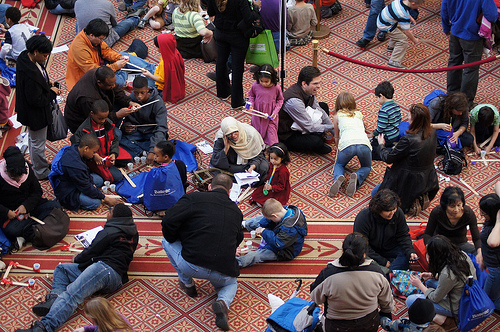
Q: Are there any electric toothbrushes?
A: No, there are no electric toothbrushes.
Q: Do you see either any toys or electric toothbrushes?
A: No, there are no electric toothbrushes or toys.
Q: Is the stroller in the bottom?
A: Yes, the stroller is in the bottom of the image.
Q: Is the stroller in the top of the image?
A: No, the stroller is in the bottom of the image.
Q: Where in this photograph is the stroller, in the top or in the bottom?
A: The stroller is in the bottom of the image.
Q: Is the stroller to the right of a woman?
A: No, the stroller is to the left of a woman.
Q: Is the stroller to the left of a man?
A: No, the stroller is to the right of a man.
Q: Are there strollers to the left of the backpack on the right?
A: Yes, there is a stroller to the left of the backpack.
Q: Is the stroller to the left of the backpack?
A: Yes, the stroller is to the left of the backpack.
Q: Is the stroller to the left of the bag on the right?
A: Yes, the stroller is to the left of the backpack.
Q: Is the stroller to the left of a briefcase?
A: No, the stroller is to the left of the backpack.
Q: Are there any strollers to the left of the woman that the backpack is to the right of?
A: Yes, there is a stroller to the left of the woman.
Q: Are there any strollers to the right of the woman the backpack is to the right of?
A: No, the stroller is to the left of the woman.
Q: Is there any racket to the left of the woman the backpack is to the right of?
A: No, there is a stroller to the left of the woman.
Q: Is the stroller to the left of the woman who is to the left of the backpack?
A: Yes, the stroller is to the left of the woman.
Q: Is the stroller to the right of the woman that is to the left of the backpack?
A: No, the stroller is to the left of the woman.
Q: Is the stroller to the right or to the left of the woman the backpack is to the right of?
A: The stroller is to the left of the woman.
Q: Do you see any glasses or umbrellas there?
A: No, there are no glasses or umbrellas.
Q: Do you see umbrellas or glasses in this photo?
A: No, there are no glasses or umbrellas.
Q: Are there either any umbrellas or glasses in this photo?
A: No, there are no glasses or umbrellas.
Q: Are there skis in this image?
A: No, there are no skis.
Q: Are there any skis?
A: No, there are no skis.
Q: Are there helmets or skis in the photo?
A: No, there are no skis or helmets.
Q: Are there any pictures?
A: No, there are no pictures.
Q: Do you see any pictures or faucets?
A: No, there are no pictures or faucets.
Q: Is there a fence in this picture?
A: No, there are no fences.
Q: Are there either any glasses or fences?
A: No, there are no fences or glasses.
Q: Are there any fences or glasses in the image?
A: No, there are no fences or glasses.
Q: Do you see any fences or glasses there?
A: No, there are no fences or glasses.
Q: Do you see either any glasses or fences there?
A: No, there are no fences or glasses.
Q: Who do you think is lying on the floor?
A: The man is lying on the floor.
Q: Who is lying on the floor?
A: The man is lying on the floor.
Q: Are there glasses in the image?
A: No, there are no glasses.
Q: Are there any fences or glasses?
A: No, there are no glasses or fences.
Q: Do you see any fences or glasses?
A: No, there are no glasses or fences.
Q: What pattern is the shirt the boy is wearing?
A: The shirt is striped.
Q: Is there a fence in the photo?
A: No, there are no fences.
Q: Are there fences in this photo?
A: No, there are no fences.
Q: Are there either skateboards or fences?
A: No, there are no fences or skateboards.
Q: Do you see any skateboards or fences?
A: No, there are no fences or skateboards.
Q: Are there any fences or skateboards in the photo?
A: No, there are no fences or skateboards.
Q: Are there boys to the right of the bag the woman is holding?
A: Yes, there is a boy to the right of the bag.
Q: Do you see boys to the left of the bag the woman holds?
A: No, the boy is to the right of the bag.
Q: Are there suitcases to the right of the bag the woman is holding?
A: No, there is a boy to the right of the bag.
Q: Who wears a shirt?
A: The boy wears a shirt.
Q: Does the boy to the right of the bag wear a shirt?
A: Yes, the boy wears a shirt.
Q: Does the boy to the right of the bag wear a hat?
A: No, the boy wears a shirt.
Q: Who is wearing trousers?
A: The boy is wearing trousers.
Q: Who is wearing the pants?
A: The boy is wearing trousers.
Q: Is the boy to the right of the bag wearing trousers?
A: Yes, the boy is wearing trousers.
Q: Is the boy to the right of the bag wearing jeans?
A: No, the boy is wearing trousers.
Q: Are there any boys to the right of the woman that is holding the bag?
A: Yes, there is a boy to the right of the woman.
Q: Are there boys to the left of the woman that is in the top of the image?
A: No, the boy is to the right of the woman.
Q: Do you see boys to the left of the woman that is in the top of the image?
A: No, the boy is to the right of the woman.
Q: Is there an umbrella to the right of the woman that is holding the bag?
A: No, there is a boy to the right of the woman.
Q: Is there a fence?
A: No, there are no fences.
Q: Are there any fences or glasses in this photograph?
A: No, there are no fences or glasses.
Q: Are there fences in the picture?
A: No, there are no fences.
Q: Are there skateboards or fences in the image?
A: No, there are no fences or skateboards.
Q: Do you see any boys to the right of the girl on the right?
A: Yes, there is a boy to the right of the girl.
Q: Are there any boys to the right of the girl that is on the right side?
A: Yes, there is a boy to the right of the girl.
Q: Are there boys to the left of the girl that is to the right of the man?
A: No, the boy is to the right of the girl.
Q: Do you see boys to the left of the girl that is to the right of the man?
A: No, the boy is to the right of the girl.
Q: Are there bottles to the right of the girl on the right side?
A: No, there is a boy to the right of the girl.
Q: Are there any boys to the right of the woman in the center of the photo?
A: Yes, there is a boy to the right of the woman.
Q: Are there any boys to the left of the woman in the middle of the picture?
A: No, the boy is to the right of the woman.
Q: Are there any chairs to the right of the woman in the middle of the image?
A: No, there is a boy to the right of the woman.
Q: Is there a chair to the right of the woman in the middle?
A: No, there is a boy to the right of the woman.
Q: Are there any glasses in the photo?
A: No, there are no glasses.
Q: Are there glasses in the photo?
A: No, there are no glasses.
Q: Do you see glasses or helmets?
A: No, there are no glasses or helmets.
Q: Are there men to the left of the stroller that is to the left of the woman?
A: Yes, there is a man to the left of the stroller.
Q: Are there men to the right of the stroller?
A: No, the man is to the left of the stroller.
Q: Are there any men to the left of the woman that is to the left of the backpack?
A: Yes, there is a man to the left of the woman.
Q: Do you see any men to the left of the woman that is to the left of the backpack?
A: Yes, there is a man to the left of the woman.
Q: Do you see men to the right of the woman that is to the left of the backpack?
A: No, the man is to the left of the woman.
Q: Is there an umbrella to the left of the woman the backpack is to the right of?
A: No, there is a man to the left of the woman.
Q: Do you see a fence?
A: No, there are no fences.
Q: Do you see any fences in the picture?
A: No, there are no fences.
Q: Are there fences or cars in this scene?
A: No, there are no fences or cars.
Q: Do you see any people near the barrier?
A: Yes, there are people near the barrier.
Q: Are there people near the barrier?
A: Yes, there are people near the barrier.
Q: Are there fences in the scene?
A: No, there are no fences.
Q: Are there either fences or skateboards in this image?
A: No, there are no fences or skateboards.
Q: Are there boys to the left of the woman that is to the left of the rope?
A: Yes, there are boys to the left of the woman.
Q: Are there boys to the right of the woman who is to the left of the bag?
A: No, the boys are to the left of the woman.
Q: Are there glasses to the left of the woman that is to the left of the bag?
A: No, there are boys to the left of the woman.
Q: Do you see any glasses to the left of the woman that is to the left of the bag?
A: No, there are boys to the left of the woman.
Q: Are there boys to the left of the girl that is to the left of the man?
A: Yes, there are boys to the left of the girl.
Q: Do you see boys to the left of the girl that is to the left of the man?
A: Yes, there are boys to the left of the girl.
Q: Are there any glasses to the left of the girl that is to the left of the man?
A: No, there are boys to the left of the girl.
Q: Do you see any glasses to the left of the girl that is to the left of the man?
A: No, there are boys to the left of the girl.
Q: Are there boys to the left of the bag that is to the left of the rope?
A: Yes, there are boys to the left of the bag.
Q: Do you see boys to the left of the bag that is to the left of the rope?
A: Yes, there are boys to the left of the bag.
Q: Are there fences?
A: No, there are no fences.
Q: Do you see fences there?
A: No, there are no fences.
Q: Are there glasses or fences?
A: No, there are no fences or glasses.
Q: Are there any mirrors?
A: No, there are no mirrors.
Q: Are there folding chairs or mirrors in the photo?
A: No, there are no mirrors or folding chairs.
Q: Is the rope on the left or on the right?
A: The rope is on the right of the image.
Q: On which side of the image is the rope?
A: The rope is on the right of the image.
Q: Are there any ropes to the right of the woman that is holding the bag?
A: Yes, there is a rope to the right of the woman.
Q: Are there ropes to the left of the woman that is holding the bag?
A: No, the rope is to the right of the woman.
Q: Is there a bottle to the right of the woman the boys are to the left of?
A: No, there is a rope to the right of the woman.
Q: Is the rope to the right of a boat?
A: No, the rope is to the right of the woman.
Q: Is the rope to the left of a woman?
A: No, the rope is to the right of a woman.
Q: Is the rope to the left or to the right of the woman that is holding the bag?
A: The rope is to the right of the woman.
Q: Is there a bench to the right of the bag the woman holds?
A: No, there is a rope to the right of the bag.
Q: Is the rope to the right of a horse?
A: No, the rope is to the right of a bag.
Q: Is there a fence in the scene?
A: No, there are no fences.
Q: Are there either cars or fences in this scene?
A: No, there are no fences or cars.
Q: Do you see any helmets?
A: No, there are no helmets.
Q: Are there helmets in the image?
A: No, there are no helmets.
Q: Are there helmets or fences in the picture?
A: No, there are no helmets or fences.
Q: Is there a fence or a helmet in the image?
A: No, there are no helmets or fences.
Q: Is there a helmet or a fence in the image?
A: No, there are no helmets or fences.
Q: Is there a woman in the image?
A: Yes, there is a woman.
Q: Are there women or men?
A: Yes, there is a woman.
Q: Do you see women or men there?
A: Yes, there is a woman.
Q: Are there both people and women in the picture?
A: Yes, there are both a woman and people.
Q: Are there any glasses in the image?
A: No, there are no glasses.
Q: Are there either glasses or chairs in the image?
A: No, there are no glasses or chairs.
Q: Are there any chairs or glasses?
A: No, there are no glasses or chairs.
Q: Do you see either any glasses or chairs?
A: No, there are no glasses or chairs.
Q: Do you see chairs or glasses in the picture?
A: No, there are no glasses or chairs.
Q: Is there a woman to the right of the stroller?
A: Yes, there is a woman to the right of the stroller.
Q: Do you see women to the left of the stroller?
A: No, the woman is to the right of the stroller.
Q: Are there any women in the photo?
A: Yes, there is a woman.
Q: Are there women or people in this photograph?
A: Yes, there is a woman.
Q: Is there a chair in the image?
A: No, there are no chairs.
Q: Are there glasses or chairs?
A: No, there are no chairs or glasses.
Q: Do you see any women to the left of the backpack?
A: Yes, there is a woman to the left of the backpack.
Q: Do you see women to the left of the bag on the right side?
A: Yes, there is a woman to the left of the backpack.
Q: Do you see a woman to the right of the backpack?
A: No, the woman is to the left of the backpack.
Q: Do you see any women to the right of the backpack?
A: No, the woman is to the left of the backpack.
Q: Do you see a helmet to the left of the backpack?
A: No, there is a woman to the left of the backpack.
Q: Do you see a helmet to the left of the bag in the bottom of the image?
A: No, there is a woman to the left of the backpack.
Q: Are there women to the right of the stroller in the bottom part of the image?
A: Yes, there is a woman to the right of the stroller.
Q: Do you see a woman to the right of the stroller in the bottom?
A: Yes, there is a woman to the right of the stroller.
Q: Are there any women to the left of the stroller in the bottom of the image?
A: No, the woman is to the right of the stroller.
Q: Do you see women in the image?
A: Yes, there is a woman.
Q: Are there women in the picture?
A: Yes, there is a woman.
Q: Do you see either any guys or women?
A: Yes, there is a woman.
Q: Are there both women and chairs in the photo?
A: No, there is a woman but no chairs.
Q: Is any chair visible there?
A: No, there are no chairs.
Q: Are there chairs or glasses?
A: No, there are no chairs or glasses.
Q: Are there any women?
A: Yes, there is a woman.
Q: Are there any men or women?
A: Yes, there is a woman.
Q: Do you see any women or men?
A: Yes, there is a woman.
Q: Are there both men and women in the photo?
A: Yes, there are both a woman and a man.